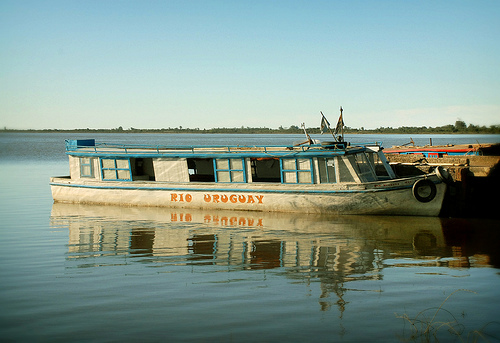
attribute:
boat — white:
[46, 107, 456, 222]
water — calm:
[2, 133, 500, 343]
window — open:
[184, 153, 219, 185]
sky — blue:
[2, 3, 498, 130]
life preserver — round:
[410, 176, 440, 205]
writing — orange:
[166, 191, 268, 210]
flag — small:
[332, 105, 348, 137]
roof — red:
[382, 143, 481, 157]